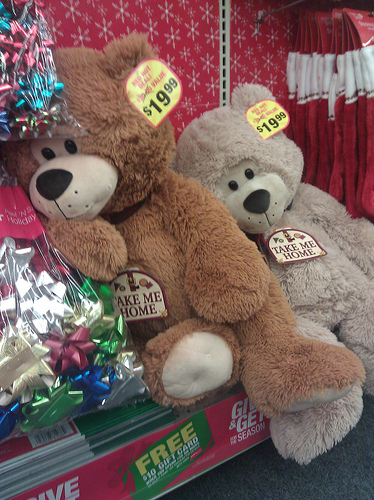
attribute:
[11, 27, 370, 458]
two teddy bears — here, for sale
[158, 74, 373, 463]
teddy bear — beige, brown, tan, gray, leaning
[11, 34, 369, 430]
teddy bear — brown, leaning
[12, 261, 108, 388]
bows — here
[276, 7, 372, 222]
stockings — red, white, hanging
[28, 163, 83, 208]
nose — brown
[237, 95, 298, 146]
tag — yellow, tan, red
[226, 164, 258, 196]
eyes — brown, small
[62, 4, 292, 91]
snowflake pattern — here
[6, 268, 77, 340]
bow — silver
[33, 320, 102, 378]
gift bow — red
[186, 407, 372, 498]
floor — gray, dark blue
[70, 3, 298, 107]
paper — red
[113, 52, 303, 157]
two tags — here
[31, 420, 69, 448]
bar code — here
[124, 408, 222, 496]
sticker — green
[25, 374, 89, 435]
bow — green